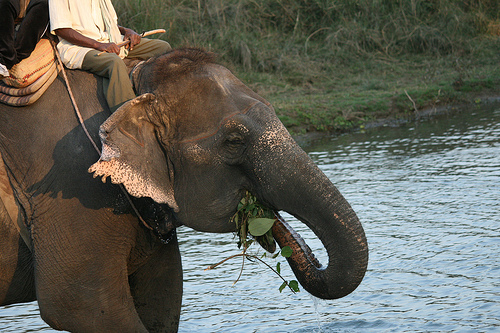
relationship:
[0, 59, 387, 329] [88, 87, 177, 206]
elephant has ear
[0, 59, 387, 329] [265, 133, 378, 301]
elephant has trunk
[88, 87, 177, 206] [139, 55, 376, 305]
ear on side of head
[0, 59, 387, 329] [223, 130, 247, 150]
elephant has eye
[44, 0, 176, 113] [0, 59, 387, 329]
man riding elephant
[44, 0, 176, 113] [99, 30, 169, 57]
man holding stick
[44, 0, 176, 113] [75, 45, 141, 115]
man has right leg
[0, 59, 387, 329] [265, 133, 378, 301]
elephant eating with trunk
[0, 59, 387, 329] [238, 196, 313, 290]
elephant eating weeds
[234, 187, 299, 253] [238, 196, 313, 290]
mouth chewing weeds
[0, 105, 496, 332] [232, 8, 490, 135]
water next to shore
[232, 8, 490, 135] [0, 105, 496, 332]
shore next to water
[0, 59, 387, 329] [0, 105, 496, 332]
elephant walking in water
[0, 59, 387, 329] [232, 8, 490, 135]
elephant near shore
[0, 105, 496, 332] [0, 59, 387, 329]
water surrounding elephant